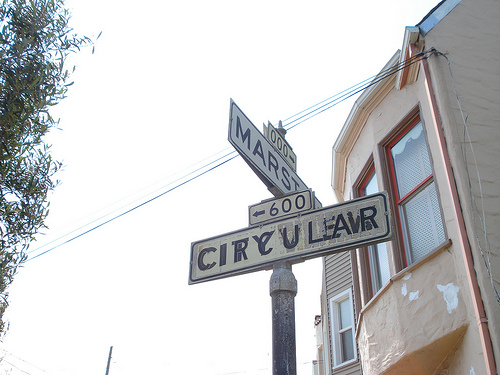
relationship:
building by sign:
[309, 0, 498, 374] [224, 96, 326, 211]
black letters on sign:
[197, 202, 378, 276] [187, 190, 395, 284]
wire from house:
[0, 32, 450, 280] [267, 32, 494, 374]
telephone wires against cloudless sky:
[12, 47, 449, 272] [2, 0, 456, 372]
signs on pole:
[226, 104, 331, 209] [269, 265, 297, 374]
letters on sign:
[234, 116, 301, 193] [228, 102, 324, 217]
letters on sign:
[196, 205, 380, 271] [187, 190, 395, 284]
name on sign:
[234, 114, 302, 194] [224, 96, 326, 211]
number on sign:
[268, 127, 290, 158] [267, 120, 296, 173]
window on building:
[375, 112, 450, 261] [309, 0, 498, 374]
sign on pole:
[187, 190, 395, 284] [269, 265, 297, 374]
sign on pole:
[224, 96, 326, 211] [269, 265, 297, 374]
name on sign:
[197, 203, 379, 270] [193, 203, 407, 262]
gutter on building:
[394, 26, 424, 88] [309, 0, 498, 374]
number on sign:
[268, 194, 308, 216] [247, 187, 314, 227]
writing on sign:
[196, 206, 381, 271] [187, 190, 395, 284]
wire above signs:
[0, 32, 450, 280] [226, 104, 331, 209]